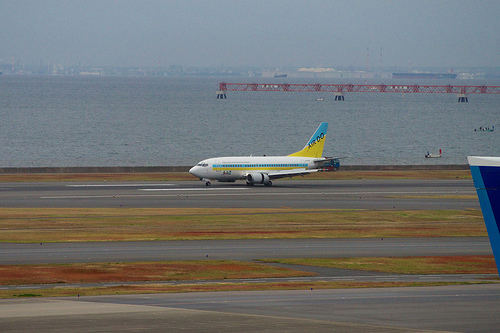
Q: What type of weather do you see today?
A: It is foggy.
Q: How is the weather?
A: It is foggy.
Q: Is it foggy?
A: Yes, it is foggy.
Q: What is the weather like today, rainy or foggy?
A: It is foggy.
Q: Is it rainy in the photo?
A: No, it is foggy.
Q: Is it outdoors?
A: Yes, it is outdoors.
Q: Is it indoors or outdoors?
A: It is outdoors.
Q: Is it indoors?
A: No, it is outdoors.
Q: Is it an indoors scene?
A: No, it is outdoors.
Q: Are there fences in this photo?
A: No, there are no fences.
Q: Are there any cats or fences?
A: No, there are no fences or cats.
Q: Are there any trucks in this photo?
A: No, there are no trucks.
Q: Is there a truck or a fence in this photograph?
A: No, there are no trucks or fences.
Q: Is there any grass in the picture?
A: Yes, there is grass.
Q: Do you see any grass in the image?
A: Yes, there is grass.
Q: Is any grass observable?
A: Yes, there is grass.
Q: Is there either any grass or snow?
A: Yes, there is grass.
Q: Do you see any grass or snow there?
A: Yes, there is grass.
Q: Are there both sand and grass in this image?
A: No, there is grass but no sand.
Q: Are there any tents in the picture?
A: No, there are no tents.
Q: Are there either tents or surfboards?
A: No, there are no tents or surfboards.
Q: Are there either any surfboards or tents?
A: No, there are no tents or surfboards.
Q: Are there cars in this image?
A: No, there are no cars.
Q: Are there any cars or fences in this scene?
A: No, there are no cars or fences.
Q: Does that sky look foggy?
A: Yes, the sky is foggy.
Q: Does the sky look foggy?
A: Yes, the sky is foggy.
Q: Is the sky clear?
A: No, the sky is foggy.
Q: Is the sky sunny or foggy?
A: The sky is foggy.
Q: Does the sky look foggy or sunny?
A: The sky is foggy.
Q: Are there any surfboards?
A: No, there are no surfboards.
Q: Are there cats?
A: No, there are no cats.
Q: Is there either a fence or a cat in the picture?
A: No, there are no cats or fences.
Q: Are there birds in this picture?
A: No, there are no birds.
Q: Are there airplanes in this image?
A: Yes, there is an airplane.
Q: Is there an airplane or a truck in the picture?
A: Yes, there is an airplane.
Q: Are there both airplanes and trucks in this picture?
A: No, there is an airplane but no trucks.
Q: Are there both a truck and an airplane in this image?
A: No, there is an airplane but no trucks.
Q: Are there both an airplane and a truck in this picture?
A: No, there is an airplane but no trucks.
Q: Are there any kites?
A: No, there are no kites.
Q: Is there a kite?
A: No, there are no kites.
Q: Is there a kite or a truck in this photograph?
A: No, there are no kites or trucks.